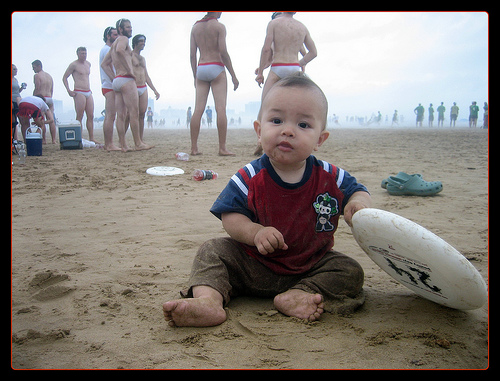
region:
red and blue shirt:
[220, 157, 355, 257]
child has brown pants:
[195, 238, 365, 303]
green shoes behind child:
[372, 147, 443, 219]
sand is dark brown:
[63, 220, 152, 298]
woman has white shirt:
[25, 90, 45, 102]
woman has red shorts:
[16, 101, 68, 136]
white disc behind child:
[148, 152, 178, 189]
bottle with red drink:
[175, 167, 228, 186]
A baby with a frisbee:
[156, 68, 488, 350]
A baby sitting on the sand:
[157, 71, 376, 332]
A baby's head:
[247, 71, 332, 168]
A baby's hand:
[250, 223, 292, 259]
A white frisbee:
[346, 203, 488, 315]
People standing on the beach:
[13, 11, 487, 161]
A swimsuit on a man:
[190, 57, 227, 88]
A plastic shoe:
[378, 166, 449, 201]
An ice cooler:
[55, 118, 87, 153]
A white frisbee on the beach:
[140, 158, 187, 183]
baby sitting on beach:
[176, 80, 363, 313]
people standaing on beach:
[19, 7, 244, 156]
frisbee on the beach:
[352, 205, 489, 311]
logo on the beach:
[372, 238, 471, 303]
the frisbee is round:
[340, 215, 485, 306]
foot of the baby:
[159, 293, 233, 334]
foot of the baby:
[265, 295, 326, 327]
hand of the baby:
[255, 218, 294, 249]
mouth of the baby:
[261, 133, 298, 160]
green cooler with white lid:
[57, 118, 82, 148]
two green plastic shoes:
[381, 166, 442, 195]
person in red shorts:
[18, 90, 55, 142]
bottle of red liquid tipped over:
[193, 168, 217, 181]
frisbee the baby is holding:
[349, 205, 484, 314]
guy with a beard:
[112, 19, 152, 153]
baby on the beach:
[157, 69, 376, 325]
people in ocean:
[10, 111, 486, 130]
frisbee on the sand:
[145, 164, 187, 178]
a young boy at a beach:
[32, 23, 498, 369]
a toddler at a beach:
[34, 23, 491, 360]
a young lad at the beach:
[51, 45, 498, 364]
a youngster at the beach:
[107, 65, 497, 351]